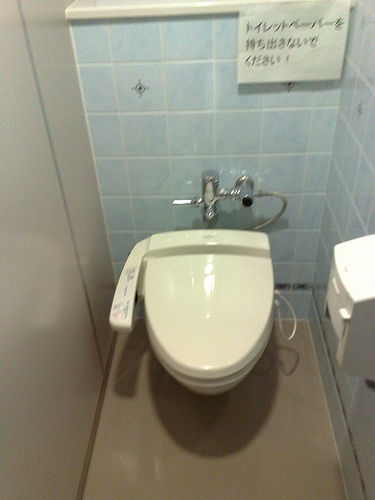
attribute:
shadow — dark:
[176, 414, 235, 447]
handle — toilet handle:
[155, 193, 213, 230]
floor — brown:
[103, 438, 244, 497]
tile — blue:
[173, 107, 315, 151]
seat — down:
[138, 255, 275, 385]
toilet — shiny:
[90, 206, 307, 405]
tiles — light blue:
[83, 60, 215, 167]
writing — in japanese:
[238, 41, 318, 77]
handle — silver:
[143, 193, 217, 217]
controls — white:
[110, 242, 156, 337]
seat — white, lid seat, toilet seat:
[107, 215, 286, 424]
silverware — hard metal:
[156, 164, 310, 225]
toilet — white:
[70, 226, 313, 395]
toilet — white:
[72, 199, 305, 403]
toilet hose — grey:
[246, 189, 290, 234]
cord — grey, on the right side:
[269, 284, 314, 349]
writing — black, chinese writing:
[246, 18, 331, 72]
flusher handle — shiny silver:
[81, 198, 298, 343]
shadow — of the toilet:
[121, 385, 305, 460]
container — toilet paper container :
[308, 239, 372, 357]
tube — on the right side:
[273, 279, 322, 390]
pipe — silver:
[189, 164, 236, 239]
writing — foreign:
[229, 16, 345, 85]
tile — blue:
[123, 112, 170, 159]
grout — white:
[96, 143, 207, 175]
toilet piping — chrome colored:
[164, 166, 305, 237]